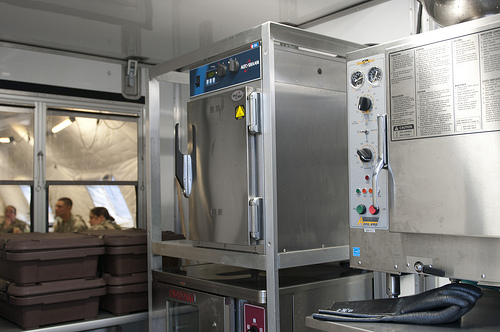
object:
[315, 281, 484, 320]
handgloves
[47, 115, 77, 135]
light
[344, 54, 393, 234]
switch buttons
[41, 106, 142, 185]
window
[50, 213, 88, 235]
uniform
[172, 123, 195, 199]
handle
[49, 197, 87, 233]
man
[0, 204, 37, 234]
soldiers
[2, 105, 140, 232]
tent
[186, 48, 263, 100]
label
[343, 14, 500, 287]
equipment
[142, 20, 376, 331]
frame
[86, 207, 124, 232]
woman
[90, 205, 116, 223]
hair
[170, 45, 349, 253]
oven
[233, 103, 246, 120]
sticker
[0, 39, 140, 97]
wall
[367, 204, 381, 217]
button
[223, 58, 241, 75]
button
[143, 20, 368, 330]
dishwasher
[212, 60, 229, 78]
knob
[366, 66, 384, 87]
round dial